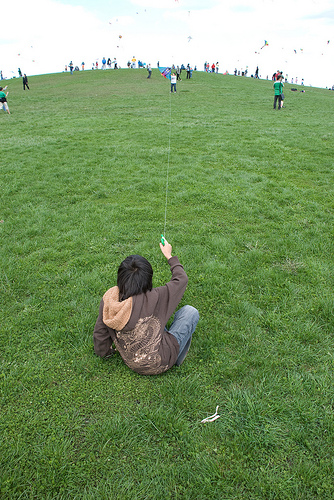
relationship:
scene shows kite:
[4, 1, 331, 496] [255, 42, 272, 56]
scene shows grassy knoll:
[4, 1, 331, 496] [6, 68, 331, 270]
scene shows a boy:
[4, 1, 331, 496] [101, 245, 197, 377]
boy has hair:
[101, 245, 197, 377] [117, 256, 153, 297]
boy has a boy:
[101, 245, 197, 377] [92, 236, 199, 373]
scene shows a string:
[4, 1, 331, 496] [160, 94, 172, 235]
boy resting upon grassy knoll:
[101, 245, 197, 377] [6, 68, 331, 270]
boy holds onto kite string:
[101, 245, 197, 377] [160, 94, 172, 235]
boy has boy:
[101, 245, 197, 377] [92, 236, 199, 373]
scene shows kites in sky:
[4, 1, 331, 496] [110, 0, 232, 41]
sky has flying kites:
[110, 0, 232, 41] [114, 32, 334, 53]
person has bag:
[271, 78, 285, 110] [281, 101, 285, 113]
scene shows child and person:
[4, 1, 331, 496] [186, 70, 194, 82]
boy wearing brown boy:
[101, 245, 197, 377] [92, 236, 199, 373]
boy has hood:
[101, 245, 197, 377] [102, 288, 133, 334]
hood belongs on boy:
[102, 288, 133, 334] [92, 236, 199, 373]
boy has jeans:
[101, 245, 197, 377] [171, 304, 200, 363]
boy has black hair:
[101, 245, 197, 377] [117, 256, 153, 297]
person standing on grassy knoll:
[271, 78, 285, 110] [6, 68, 331, 270]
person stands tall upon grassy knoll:
[271, 78, 285, 110] [6, 68, 331, 270]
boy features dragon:
[92, 236, 199, 373] [118, 318, 163, 368]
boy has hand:
[101, 245, 197, 377] [158, 244, 173, 257]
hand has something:
[158, 244, 173, 257] [161, 235, 168, 243]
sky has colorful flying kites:
[110, 0, 232, 41] [114, 32, 334, 53]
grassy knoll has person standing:
[6, 68, 331, 270] [255, 68, 258, 80]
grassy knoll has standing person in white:
[6, 68, 331, 270] [170, 75, 180, 96]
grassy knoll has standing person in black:
[6, 68, 331, 270] [23, 75, 32, 89]